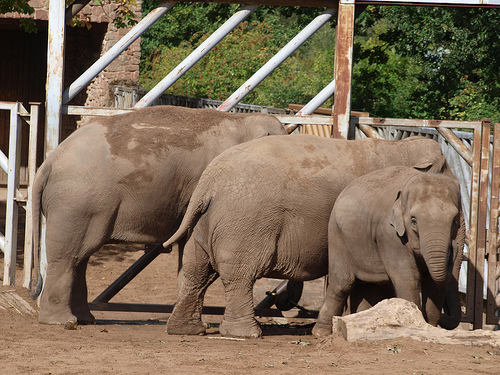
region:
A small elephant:
[312, 165, 467, 333]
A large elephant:
[163, 133, 450, 339]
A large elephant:
[26, 107, 288, 327]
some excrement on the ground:
[63, 318, 75, 332]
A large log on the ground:
[331, 298, 499, 348]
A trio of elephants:
[24, 109, 464, 332]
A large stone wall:
[0, 0, 144, 126]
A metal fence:
[1, 100, 499, 336]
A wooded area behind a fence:
[139, 0, 498, 118]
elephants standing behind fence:
[28, 90, 472, 349]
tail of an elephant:
[161, 186, 201, 251]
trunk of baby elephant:
[414, 215, 454, 283]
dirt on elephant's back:
[106, 104, 214, 139]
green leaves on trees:
[363, 8, 476, 128]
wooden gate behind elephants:
[1, 93, 33, 286]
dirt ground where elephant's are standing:
[47, 346, 267, 364]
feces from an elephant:
[56, 318, 91, 340]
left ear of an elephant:
[377, 182, 413, 245]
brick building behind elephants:
[72, 1, 137, 98]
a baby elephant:
[316, 170, 461, 342]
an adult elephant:
[164, 134, 448, 347]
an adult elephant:
[23, 114, 295, 324]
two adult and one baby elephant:
[40, 108, 465, 342]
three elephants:
[26, 107, 489, 339]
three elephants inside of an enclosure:
[7, 15, 491, 339]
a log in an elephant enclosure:
[330, 300, 485, 344]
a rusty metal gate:
[307, 84, 493, 323]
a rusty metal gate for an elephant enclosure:
[363, 105, 498, 319]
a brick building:
[1, 0, 177, 108]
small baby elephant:
[314, 168, 462, 338]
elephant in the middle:
[163, 138, 467, 340]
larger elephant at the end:
[29, 110, 288, 320]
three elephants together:
[31, 106, 464, 328]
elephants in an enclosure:
[25, 106, 465, 335]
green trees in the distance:
[142, 1, 497, 119]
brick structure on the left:
[4, 0, 138, 200]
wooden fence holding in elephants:
[0, 98, 498, 325]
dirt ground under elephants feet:
[0, 232, 497, 372]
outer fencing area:
[116, 83, 491, 246]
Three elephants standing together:
[18, 91, 476, 318]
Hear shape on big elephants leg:
[36, 269, 77, 335]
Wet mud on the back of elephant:
[106, 91, 230, 179]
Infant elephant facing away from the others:
[317, 163, 467, 337]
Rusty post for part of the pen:
[324, 10, 368, 130]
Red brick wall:
[74, 11, 147, 93]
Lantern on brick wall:
[110, 71, 140, 122]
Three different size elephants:
[18, 92, 490, 373]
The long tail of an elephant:
[25, 155, 44, 315]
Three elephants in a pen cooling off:
[11, 47, 487, 373]